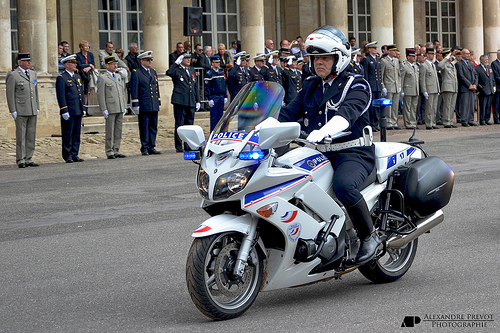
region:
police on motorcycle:
[188, 20, 490, 328]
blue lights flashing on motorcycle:
[149, 110, 276, 177]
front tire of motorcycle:
[170, 223, 263, 330]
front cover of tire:
[180, 215, 280, 325]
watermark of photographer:
[395, 305, 496, 330]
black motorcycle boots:
[337, 189, 389, 274]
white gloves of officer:
[300, 112, 355, 154]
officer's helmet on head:
[294, 18, 359, 83]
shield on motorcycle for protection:
[214, 62, 287, 178]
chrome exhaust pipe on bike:
[379, 206, 446, 261]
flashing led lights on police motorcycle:
[151, 126, 291, 200]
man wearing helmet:
[293, 17, 365, 77]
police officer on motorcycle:
[196, 19, 431, 281]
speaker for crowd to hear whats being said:
[177, 0, 209, 46]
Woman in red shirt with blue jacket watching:
[69, 31, 97, 73]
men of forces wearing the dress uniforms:
[2, 44, 165, 168]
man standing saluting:
[165, 45, 203, 157]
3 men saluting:
[226, 42, 308, 90]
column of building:
[16, 0, 68, 42]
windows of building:
[91, 5, 146, 35]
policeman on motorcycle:
[142, 12, 478, 307]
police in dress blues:
[270, 13, 396, 278]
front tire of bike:
[177, 206, 272, 325]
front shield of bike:
[197, 86, 262, 214]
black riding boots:
[335, 195, 393, 275]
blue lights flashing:
[175, 150, 265, 167]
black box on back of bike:
[388, 155, 469, 222]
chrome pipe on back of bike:
[376, 209, 451, 235]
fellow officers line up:
[0, 43, 165, 167]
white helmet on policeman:
[295, 26, 362, 91]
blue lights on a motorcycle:
[177, 145, 204, 164]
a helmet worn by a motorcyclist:
[297, 22, 364, 88]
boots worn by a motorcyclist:
[331, 189, 391, 278]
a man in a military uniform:
[128, 46, 163, 156]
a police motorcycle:
[161, 67, 474, 330]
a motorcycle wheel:
[173, 200, 278, 324]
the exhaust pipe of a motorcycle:
[383, 195, 463, 268]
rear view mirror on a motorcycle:
[243, 105, 308, 162]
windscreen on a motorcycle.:
[207, 75, 294, 138]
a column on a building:
[128, 0, 178, 82]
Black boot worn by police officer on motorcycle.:
[341, 199, 389, 268]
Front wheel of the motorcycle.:
[187, 229, 272, 319]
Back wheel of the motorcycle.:
[372, 221, 415, 279]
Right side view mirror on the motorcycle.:
[257, 120, 298, 151]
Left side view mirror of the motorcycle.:
[174, 116, 203, 151]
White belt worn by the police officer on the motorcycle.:
[308, 141, 370, 150]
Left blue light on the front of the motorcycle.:
[183, 146, 204, 159]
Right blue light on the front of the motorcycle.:
[236, 147, 267, 157]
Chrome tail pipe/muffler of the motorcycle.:
[383, 208, 448, 243]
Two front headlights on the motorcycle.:
[197, 163, 249, 199]